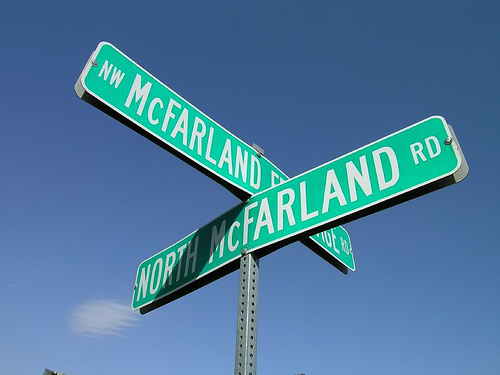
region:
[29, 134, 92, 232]
the sky is clear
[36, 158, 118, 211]
the sky is clear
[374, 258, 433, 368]
the sky is clear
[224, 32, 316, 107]
the sky is clear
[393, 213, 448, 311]
the sky is clear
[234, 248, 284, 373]
the bar is gray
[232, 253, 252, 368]
the bar is gray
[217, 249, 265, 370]
the bar is gray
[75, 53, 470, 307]
white and green street signs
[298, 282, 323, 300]
white clouds in blue sky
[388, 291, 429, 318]
white clouds in blue sky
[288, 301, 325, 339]
white clouds in blue sky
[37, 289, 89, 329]
white clouds in blue sky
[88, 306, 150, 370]
white clouds in blue sky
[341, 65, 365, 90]
white clouds in blue sky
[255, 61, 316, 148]
white clouds in blue sky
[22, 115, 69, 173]
white clouds in blue sky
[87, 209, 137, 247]
white clouds in blue sky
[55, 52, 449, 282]
green and white street signs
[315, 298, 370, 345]
white clouds in blue sky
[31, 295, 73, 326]
white clouds in blue sky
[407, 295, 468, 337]
white clouds in blue sky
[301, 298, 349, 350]
white clouds in blue sky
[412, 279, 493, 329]
white clouds in blue sky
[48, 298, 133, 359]
white clouds in blue sky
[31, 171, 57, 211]
white clouds in blue sky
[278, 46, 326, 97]
white clouds in blue sky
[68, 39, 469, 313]
street signs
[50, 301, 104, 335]
white clouds in blue sky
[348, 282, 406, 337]
white clouds in blue sky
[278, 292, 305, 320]
white clouds in blue sky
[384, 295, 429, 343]
white clouds in blue sky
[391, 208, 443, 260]
white clouds in blue sky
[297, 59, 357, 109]
white clouds in blue sky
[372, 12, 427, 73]
white clouds in blue sky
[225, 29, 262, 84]
white clouds in blue sky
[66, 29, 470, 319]
these street signs have similar names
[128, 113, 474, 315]
one street is called North McFarland Rd.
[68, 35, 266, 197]
the other street is also called McFarland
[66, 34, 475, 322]
the street signs are green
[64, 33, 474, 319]
the lettering on the street signs is white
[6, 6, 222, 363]
only one little cloud in the sky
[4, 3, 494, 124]
the sky is mostly a clear cloudless blue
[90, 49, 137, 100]
the designation "NW" indicates which way the street runs